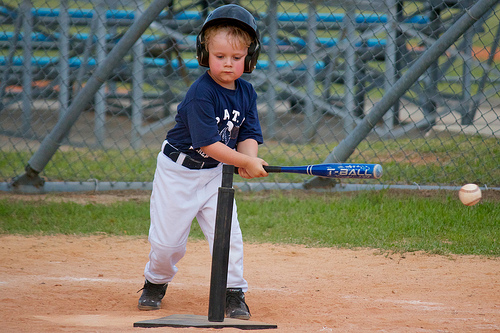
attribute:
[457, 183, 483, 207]
baseball — red, white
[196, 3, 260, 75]
helmet — black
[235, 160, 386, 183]
bat — blue, metal, short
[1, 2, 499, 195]
fence — chain link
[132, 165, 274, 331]
stand — black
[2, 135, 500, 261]
grass — green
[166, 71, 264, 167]
shirt — blue, navy blue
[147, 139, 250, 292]
pants — white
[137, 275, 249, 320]
cleats — black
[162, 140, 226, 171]
belt — black